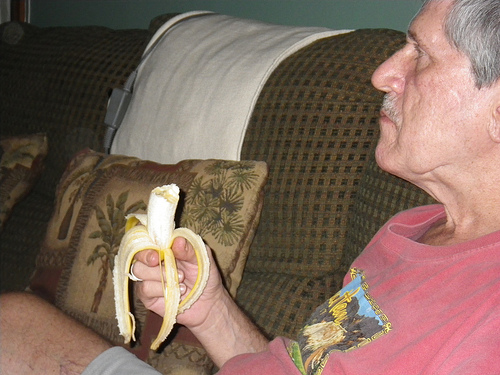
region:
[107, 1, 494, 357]
a man holding a banana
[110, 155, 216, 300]
a half eaten banana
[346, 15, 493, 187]
a man with facial hair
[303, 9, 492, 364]
a man wearing a red tee shirt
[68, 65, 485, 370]
a man holding a peeled banana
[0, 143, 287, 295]
a pillow with a palm tree picture on it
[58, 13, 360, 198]
a white blanket on the back of a couch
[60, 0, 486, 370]
a man wearing grey shorts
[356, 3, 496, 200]
a man with grey hair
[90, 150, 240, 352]
a peeled banana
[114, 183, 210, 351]
A banana on person's hand.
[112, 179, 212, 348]
A peeled banana.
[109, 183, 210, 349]
A banana that is half eaten.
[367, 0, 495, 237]
A man's left side of face.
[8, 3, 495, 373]
A man sitting on a couch.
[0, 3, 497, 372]
An elderly man sitting on a brown checkered couch.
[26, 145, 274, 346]
A flowered pillow.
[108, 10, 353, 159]
A white cloth.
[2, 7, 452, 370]
A brown checkered couch.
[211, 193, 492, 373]
A red tee-shirt.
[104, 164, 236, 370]
a partially eaten banana in a man's hand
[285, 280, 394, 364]
an image on the front of a shirt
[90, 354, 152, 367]
tan khaki shorts on a man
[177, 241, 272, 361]
a man's right arm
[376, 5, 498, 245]
the side of a man's face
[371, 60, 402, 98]
the left side of a man's nose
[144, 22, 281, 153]
a white electric blanket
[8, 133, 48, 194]
the corner of a pillow to the left of another pillow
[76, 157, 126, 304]
a tropical motif on a pillow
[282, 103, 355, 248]
a brown checkered couch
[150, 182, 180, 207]
a bite mark on a banana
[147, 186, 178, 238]
a half eaten banana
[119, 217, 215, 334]
a banana peel in a man's hand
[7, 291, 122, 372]
a bare leg of a man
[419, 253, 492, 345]
a pink shirt on a man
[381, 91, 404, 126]
a grey and white mustache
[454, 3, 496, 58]
salt and pepper hair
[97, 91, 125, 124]
the remote control on an electric blanket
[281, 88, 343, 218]
a brown checkered back of a couch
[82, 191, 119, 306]
a palm tree on a pillow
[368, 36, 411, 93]
The man has a nose.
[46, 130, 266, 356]
A pillow on the couch.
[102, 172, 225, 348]
The man is holding a banana.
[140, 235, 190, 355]
Part of the banana peal.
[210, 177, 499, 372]
The man is wearing a pink shirt.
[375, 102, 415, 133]
The man has a mouth.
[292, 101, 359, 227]
Part of the couch is brown.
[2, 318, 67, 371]
Part of the man's leg is bare.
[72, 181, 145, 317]
A palm tree on the pillow.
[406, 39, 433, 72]
An eye on a man.